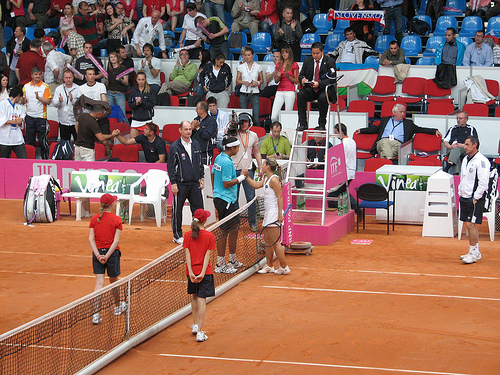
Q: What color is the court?
A: Brown.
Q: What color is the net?
A: White.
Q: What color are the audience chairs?
A: Red and blue.